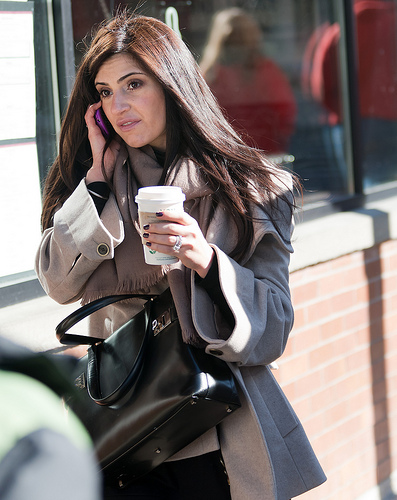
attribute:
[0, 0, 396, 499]
building — brick, red brick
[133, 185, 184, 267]
coffee cup — cofee cup, disposable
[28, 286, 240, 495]
handbag — leather, black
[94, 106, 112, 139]
cell phone — purple, pink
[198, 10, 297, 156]
reflection — blonde, of a person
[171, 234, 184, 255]
ring — large, shiny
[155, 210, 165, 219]
fingernails — painted, purple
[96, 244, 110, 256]
button — big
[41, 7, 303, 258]
hair — shiny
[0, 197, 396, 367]
ledge — cement